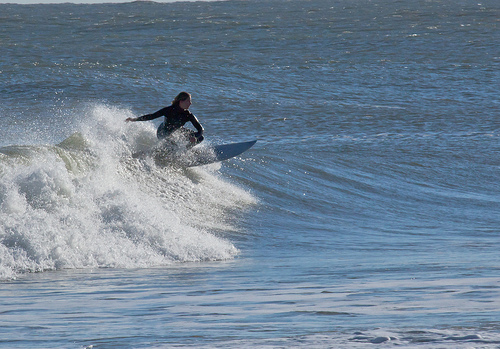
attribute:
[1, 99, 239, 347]
wave — white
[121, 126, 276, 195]
surfboard — blue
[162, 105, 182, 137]
wetsuit — dark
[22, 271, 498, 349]
water — flat and blue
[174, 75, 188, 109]
hair — short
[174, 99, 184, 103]
hair — brown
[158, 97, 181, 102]
hair — long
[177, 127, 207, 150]
leg — bent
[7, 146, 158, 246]
wave — white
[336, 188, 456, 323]
water — blue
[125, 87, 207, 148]
lady — light skinned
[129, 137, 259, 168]
board — blue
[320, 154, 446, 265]
water — calm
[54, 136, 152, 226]
wave — white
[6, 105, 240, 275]
wave — large, breaking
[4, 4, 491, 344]
ocean water — clear, blue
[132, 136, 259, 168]
surfboard — blue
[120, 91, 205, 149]
surfer — female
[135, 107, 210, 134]
wetsuit — black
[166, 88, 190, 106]
hair — long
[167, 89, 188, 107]
hair — long, dark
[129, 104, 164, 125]
arm — extended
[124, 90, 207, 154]
surfer — female